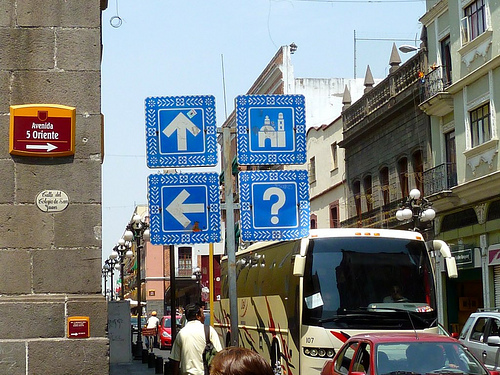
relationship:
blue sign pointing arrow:
[144, 95, 218, 168] [148, 99, 211, 161]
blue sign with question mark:
[239, 167, 311, 242] [258, 182, 288, 225]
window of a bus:
[298, 231, 439, 331] [198, 226, 455, 373]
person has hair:
[201, 340, 271, 370] [226, 354, 248, 369]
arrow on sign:
[159, 182, 208, 232] [144, 168, 227, 248]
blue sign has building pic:
[146, 97, 216, 166] [247, 106, 295, 153]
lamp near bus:
[392, 183, 439, 230] [210, 220, 445, 374]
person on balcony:
[413, 67, 432, 95] [409, 65, 451, 122]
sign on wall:
[9, 101, 75, 163] [0, 0, 110, 375]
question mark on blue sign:
[261, 187, 286, 224] [239, 170, 310, 242]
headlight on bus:
[300, 343, 340, 357] [210, 220, 445, 374]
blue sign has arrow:
[147, 172, 220, 246] [162, 188, 206, 230]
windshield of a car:
[367, 341, 487, 373] [318, 333, 483, 372]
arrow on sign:
[159, 110, 202, 152] [143, 95, 217, 163]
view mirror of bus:
[441, 240, 459, 281] [306, 215, 444, 345]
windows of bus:
[222, 247, 298, 294] [210, 220, 445, 374]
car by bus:
[318, 330, 498, 372] [210, 220, 445, 374]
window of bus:
[302, 237, 439, 331] [210, 220, 445, 374]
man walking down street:
[168, 302, 222, 375] [111, 291, 133, 371]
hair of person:
[204, 344, 270, 372] [199, 338, 269, 373]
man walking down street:
[161, 288, 217, 361] [121, 303, 262, 372]